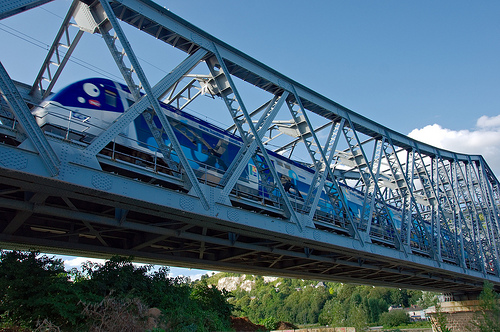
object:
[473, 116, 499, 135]
cloud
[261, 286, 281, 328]
tree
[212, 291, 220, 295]
leaves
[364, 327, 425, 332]
ground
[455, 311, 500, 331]
wall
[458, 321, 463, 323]
brick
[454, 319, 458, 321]
brick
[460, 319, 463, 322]
brick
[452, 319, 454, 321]
brick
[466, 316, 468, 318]
brick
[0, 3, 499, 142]
blue sky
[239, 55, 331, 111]
bridge beam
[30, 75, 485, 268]
train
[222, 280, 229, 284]
rocks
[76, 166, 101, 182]
metal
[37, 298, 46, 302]
leaves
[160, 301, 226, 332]
bush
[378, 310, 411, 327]
bush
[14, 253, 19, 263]
leaves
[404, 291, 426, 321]
house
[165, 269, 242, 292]
distance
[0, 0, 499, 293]
bridge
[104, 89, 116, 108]
windows